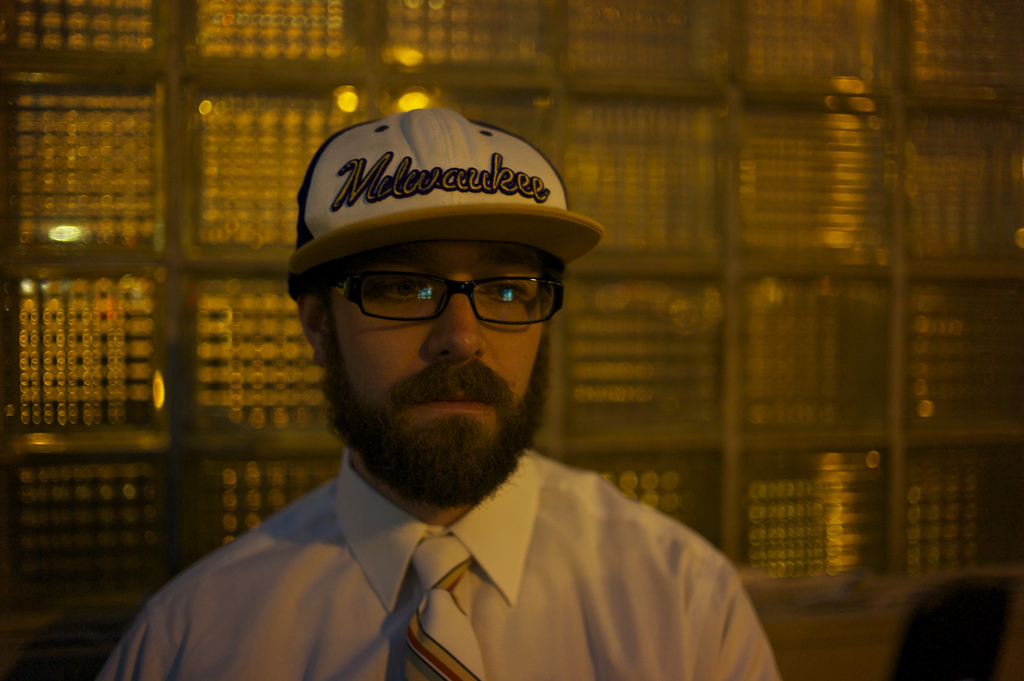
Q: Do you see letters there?
A: Yes, there are letters.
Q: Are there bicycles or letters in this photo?
A: Yes, there are letters.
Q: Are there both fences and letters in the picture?
A: No, there are letters but no fences.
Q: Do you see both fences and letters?
A: No, there are letters but no fences.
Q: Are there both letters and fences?
A: No, there are letters but no fences.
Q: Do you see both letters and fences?
A: No, there are letters but no fences.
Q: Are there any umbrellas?
A: No, there are no umbrellas.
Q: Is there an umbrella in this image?
A: No, there are no umbrellas.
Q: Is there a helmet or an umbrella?
A: No, there are no umbrellas or helmets.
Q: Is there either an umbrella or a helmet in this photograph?
A: No, there are no umbrellas or helmets.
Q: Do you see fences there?
A: No, there are no fences.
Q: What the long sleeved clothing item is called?
A: The clothing item is a dress shirt.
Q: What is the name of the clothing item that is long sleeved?
A: The clothing item is a dress shirt.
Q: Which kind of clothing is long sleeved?
A: The clothing is a dress shirt.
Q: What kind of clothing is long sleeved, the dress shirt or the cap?
A: The dress shirt is long sleeved.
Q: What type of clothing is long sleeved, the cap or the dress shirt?
A: The dress shirt is long sleeved.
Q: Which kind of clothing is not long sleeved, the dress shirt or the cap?
A: The cap is not long sleeved.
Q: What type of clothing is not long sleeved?
A: The clothing is a cap.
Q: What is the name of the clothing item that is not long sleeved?
A: The clothing item is a cap.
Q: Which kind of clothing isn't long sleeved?
A: The clothing is a cap.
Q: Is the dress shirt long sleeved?
A: Yes, the dress shirt is long sleeved.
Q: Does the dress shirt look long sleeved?
A: Yes, the dress shirt is long sleeved.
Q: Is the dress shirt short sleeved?
A: No, the dress shirt is long sleeved.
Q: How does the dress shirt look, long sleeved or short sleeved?
A: The dress shirt is long sleeved.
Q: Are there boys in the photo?
A: No, there are no boys.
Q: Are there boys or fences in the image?
A: No, there are no boys or fences.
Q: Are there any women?
A: No, there are no women.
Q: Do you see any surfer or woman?
A: No, there are no women or surfers.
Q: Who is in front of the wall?
A: The man is in front of the wall.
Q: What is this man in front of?
A: The man is in front of the wall.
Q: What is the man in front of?
A: The man is in front of the wall.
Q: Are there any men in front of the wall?
A: Yes, there is a man in front of the wall.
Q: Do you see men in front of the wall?
A: Yes, there is a man in front of the wall.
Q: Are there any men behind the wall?
A: No, the man is in front of the wall.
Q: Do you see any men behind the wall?
A: No, the man is in front of the wall.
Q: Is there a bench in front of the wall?
A: No, there is a man in front of the wall.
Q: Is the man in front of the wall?
A: Yes, the man is in front of the wall.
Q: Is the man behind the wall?
A: No, the man is in front of the wall.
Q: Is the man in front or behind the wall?
A: The man is in front of the wall.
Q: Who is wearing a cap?
A: The man is wearing a cap.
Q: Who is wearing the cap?
A: The man is wearing a cap.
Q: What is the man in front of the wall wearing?
A: The man is wearing a cap.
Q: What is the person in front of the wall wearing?
A: The man is wearing a cap.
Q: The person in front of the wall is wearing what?
A: The man is wearing a cap.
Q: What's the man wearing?
A: The man is wearing a cap.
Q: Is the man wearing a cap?
A: Yes, the man is wearing a cap.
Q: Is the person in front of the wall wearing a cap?
A: Yes, the man is wearing a cap.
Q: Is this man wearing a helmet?
A: No, the man is wearing a cap.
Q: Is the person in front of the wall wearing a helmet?
A: No, the man is wearing a cap.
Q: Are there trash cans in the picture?
A: No, there are no trash cans.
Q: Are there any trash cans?
A: No, there are no trash cans.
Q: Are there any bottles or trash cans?
A: No, there are no trash cans or bottles.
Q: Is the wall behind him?
A: Yes, the wall is behind the man.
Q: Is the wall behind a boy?
A: No, the wall is behind the man.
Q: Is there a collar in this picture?
A: Yes, there is a collar.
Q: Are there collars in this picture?
A: Yes, there is a collar.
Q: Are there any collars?
A: Yes, there is a collar.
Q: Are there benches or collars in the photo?
A: Yes, there is a collar.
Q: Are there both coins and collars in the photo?
A: No, there is a collar but no coins.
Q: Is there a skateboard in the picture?
A: No, there are no skateboards.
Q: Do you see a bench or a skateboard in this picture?
A: No, there are no skateboards or benches.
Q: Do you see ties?
A: Yes, there is a tie.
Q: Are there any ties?
A: Yes, there is a tie.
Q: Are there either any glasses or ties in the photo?
A: Yes, there is a tie.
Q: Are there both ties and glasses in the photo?
A: Yes, there are both a tie and glasses.